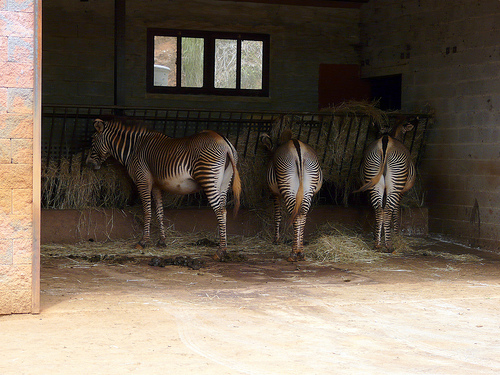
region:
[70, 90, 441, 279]
Three Zebras eating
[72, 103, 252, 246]
One zebra turned to left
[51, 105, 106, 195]
A metal hay feeder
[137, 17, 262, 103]
Window over hay feeder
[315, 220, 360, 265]
Hay on the floor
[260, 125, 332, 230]
Back end of a zebra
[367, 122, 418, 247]
Back end of a zebra turned a little to the right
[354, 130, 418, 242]
Back end of zebra swishing tail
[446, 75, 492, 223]
White and tan brick wall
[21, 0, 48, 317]
A brown trim on doorway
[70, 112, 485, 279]
three zebras eating hay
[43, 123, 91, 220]
metal grate with hay in it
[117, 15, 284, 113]
windows above the hay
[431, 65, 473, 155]
grey cement block wall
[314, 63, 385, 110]
red door behind the hay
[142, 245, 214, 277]
zebra poop on the floor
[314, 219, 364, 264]
hay on the ground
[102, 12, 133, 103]
metal beam up against the wall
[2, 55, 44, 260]
block wall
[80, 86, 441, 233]
zebras in a stall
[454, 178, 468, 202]
edge of a wall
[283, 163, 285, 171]
back of a zebra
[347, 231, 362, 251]
part of the grass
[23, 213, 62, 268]
edge of a wall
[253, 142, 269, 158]
part of the grass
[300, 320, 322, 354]
part of the surface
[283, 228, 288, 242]
part of a tail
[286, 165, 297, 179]
back of a zebra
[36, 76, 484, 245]
three zebras in the photo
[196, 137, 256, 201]
back of the zebra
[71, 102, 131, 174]
head of the zebra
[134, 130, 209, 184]
black and white body of zebra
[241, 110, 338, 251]
zebra with back facing camera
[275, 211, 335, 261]
back legs of the zebra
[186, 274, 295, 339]
ground under the zebras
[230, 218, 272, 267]
hay on the ground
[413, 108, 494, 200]
wall next to zebra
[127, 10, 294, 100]
window in the room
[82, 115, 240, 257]
a zebra is eating hay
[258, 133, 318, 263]
a zebra is eating hay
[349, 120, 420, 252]
a zebra is eating hay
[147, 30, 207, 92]
window in a brick wall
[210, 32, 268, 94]
window in a brick wall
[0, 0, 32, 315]
a brick wall on the outside of a building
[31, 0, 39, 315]
a rusted metal railing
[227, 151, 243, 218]
tail of a horse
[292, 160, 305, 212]
tail of a horse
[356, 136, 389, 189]
tail of a horse